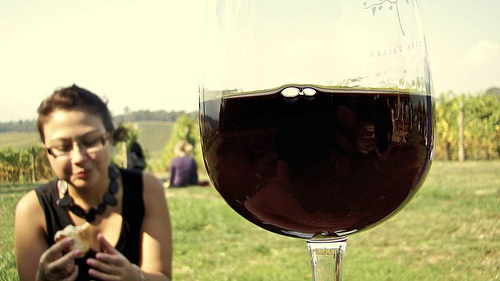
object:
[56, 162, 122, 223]
necklace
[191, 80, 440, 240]
wine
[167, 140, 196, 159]
hair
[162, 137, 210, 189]
woman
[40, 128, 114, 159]
glasses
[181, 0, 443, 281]
glass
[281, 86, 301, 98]
bubbles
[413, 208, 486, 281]
grass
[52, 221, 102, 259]
bread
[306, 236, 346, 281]
stem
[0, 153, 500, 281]
field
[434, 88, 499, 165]
trees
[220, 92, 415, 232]
reflection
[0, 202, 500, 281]
down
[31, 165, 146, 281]
tank top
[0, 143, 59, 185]
corn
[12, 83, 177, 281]
girl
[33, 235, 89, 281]
hands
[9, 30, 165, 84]
clouds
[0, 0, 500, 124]
sky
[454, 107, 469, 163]
post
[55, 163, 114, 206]
neck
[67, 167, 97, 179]
lipstick